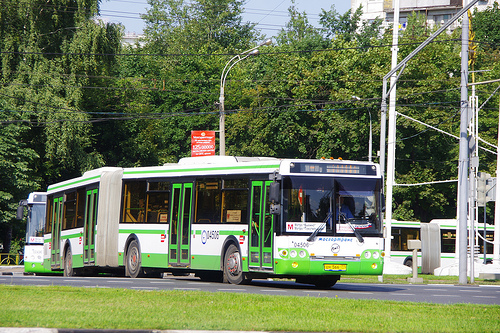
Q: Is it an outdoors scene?
A: Yes, it is outdoors.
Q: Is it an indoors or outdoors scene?
A: It is outdoors.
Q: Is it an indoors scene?
A: No, it is outdoors.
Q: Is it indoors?
A: No, it is outdoors.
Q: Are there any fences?
A: No, there are no fences.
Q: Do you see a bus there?
A: Yes, there is a bus.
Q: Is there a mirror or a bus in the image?
A: Yes, there is a bus.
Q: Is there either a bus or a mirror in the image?
A: Yes, there is a bus.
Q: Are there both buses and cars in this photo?
A: No, there is a bus but no cars.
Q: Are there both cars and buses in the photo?
A: No, there is a bus but no cars.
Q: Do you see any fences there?
A: No, there are no fences.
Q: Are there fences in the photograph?
A: No, there are no fences.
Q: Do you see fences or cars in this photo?
A: No, there are no fences or cars.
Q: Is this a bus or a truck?
A: This is a bus.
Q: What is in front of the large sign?
A: The bus is in front of the sign.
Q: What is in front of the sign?
A: The bus is in front of the sign.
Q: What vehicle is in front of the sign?
A: The vehicle is a bus.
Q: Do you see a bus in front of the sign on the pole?
A: Yes, there is a bus in front of the sign.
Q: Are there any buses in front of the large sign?
A: Yes, there is a bus in front of the sign.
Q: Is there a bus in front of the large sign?
A: Yes, there is a bus in front of the sign.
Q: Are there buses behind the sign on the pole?
A: No, the bus is in front of the sign.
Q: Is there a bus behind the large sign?
A: No, the bus is in front of the sign.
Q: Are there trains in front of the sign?
A: No, there is a bus in front of the sign.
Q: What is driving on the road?
A: The bus is driving on the road.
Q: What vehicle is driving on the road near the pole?
A: The vehicle is a bus.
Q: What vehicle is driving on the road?
A: The vehicle is a bus.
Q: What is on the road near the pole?
A: The bus is on the road.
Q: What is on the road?
A: The bus is on the road.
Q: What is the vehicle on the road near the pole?
A: The vehicle is a bus.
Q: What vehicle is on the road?
A: The vehicle is a bus.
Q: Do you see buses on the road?
A: Yes, there is a bus on the road.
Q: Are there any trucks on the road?
A: No, there is a bus on the road.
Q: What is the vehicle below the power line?
A: The vehicle is a bus.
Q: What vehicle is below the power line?
A: The vehicle is a bus.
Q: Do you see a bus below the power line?
A: Yes, there is a bus below the power line.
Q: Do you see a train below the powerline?
A: No, there is a bus below the powerline.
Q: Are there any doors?
A: Yes, there is a door.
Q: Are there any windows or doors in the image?
A: Yes, there is a door.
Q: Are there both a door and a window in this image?
A: Yes, there are both a door and a window.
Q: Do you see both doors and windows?
A: Yes, there are both a door and a window.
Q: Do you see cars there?
A: No, there are no cars.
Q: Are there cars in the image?
A: No, there are no cars.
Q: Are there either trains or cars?
A: No, there are no cars or trains.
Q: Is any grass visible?
A: Yes, there is grass.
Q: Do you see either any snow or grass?
A: Yes, there is grass.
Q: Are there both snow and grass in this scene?
A: No, there is grass but no snow.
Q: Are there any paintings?
A: No, there are no paintings.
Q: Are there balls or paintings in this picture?
A: No, there are no paintings or balls.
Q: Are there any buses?
A: Yes, there is a bus.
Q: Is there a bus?
A: Yes, there is a bus.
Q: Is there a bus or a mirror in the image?
A: Yes, there is a bus.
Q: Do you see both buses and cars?
A: No, there is a bus but no cars.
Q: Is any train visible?
A: No, there are no trains.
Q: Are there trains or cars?
A: No, there are no trains or cars.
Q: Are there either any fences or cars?
A: No, there are no cars or fences.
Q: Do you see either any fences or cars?
A: No, there are no cars or fences.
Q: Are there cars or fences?
A: No, there are no cars or fences.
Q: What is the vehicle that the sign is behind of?
A: The vehicle is a bus.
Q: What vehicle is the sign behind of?
A: The sign is behind the bus.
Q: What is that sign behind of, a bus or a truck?
A: The sign is behind a bus.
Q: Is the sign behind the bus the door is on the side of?
A: Yes, the sign is behind the bus.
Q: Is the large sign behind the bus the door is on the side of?
A: Yes, the sign is behind the bus.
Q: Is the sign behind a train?
A: No, the sign is behind the bus.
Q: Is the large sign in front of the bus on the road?
A: No, the sign is behind the bus.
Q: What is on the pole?
A: The sign is on the pole.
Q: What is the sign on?
A: The sign is on the pole.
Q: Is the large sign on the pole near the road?
A: Yes, the sign is on the pole.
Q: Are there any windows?
A: Yes, there is a window.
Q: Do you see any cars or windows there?
A: Yes, there is a window.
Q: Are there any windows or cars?
A: Yes, there is a window.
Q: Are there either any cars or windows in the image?
A: Yes, there is a window.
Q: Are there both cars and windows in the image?
A: No, there is a window but no cars.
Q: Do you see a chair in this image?
A: No, there are no chairs.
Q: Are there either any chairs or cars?
A: No, there are no chairs or cars.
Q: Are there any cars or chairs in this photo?
A: No, there are no chairs or cars.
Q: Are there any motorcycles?
A: No, there are no motorcycles.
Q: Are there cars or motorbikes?
A: No, there are no motorbikes or cars.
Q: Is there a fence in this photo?
A: No, there are no fences.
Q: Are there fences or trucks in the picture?
A: No, there are no fences or trucks.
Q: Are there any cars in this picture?
A: No, there are no cars.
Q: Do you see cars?
A: No, there are no cars.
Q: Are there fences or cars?
A: No, there are no cars or fences.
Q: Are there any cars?
A: No, there are no cars.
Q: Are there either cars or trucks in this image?
A: No, there are no cars or trucks.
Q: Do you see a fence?
A: No, there are no fences.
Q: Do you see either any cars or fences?
A: No, there are no fences or cars.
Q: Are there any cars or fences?
A: No, there are no fences or cars.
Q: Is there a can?
A: No, there are no cans.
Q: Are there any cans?
A: No, there are no cans.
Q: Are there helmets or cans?
A: No, there are no cans or helmets.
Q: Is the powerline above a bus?
A: Yes, the powerline is above a bus.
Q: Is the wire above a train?
A: No, the wire is above a bus.